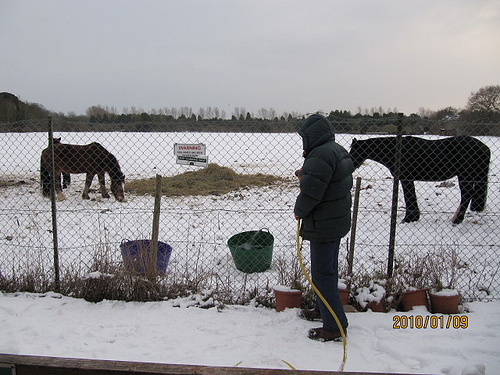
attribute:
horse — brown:
[34, 110, 127, 219]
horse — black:
[348, 132, 491, 224]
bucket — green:
[225, 231, 275, 274]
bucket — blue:
[120, 235, 172, 273]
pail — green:
[201, 196, 294, 278]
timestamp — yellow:
[393, 312, 468, 332]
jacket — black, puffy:
[301, 113, 350, 233]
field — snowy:
[10, 131, 498, 288]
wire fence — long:
[0, 116, 498, 294]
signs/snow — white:
[167, 133, 212, 169]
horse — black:
[287, 129, 497, 238]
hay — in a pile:
[117, 160, 284, 206]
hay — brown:
[130, 165, 255, 197]